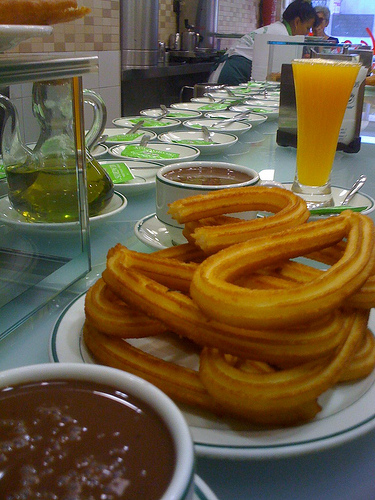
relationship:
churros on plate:
[82, 187, 373, 428] [52, 261, 374, 461]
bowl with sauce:
[0, 363, 196, 499] [2, 379, 177, 500]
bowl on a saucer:
[0, 363, 196, 499] [194, 471, 218, 499]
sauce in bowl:
[2, 379, 177, 500] [0, 363, 196, 499]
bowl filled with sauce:
[0, 363, 196, 499] [2, 379, 177, 500]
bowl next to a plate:
[0, 363, 196, 499] [52, 261, 374, 461]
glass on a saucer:
[291, 58, 361, 201] [264, 182, 374, 216]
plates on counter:
[3, 78, 374, 460] [1, 80, 374, 500]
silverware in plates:
[58, 77, 280, 184] [3, 78, 374, 460]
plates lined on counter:
[3, 78, 374, 460] [1, 80, 374, 500]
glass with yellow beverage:
[291, 58, 361, 201] [293, 63, 360, 185]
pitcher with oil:
[0, 82, 114, 223] [6, 153, 115, 224]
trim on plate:
[194, 412, 374, 451] [52, 261, 374, 461]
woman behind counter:
[207, 0, 322, 86] [1, 80, 374, 500]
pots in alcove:
[162, 21, 224, 63] [122, 0, 234, 116]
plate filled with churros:
[52, 261, 374, 461] [82, 187, 373, 428]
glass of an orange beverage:
[291, 58, 361, 201] [293, 63, 360, 185]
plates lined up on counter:
[3, 78, 374, 460] [1, 80, 374, 500]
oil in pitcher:
[6, 153, 115, 224] [0, 82, 114, 223]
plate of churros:
[52, 261, 374, 461] [82, 187, 373, 428]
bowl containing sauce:
[0, 363, 196, 499] [2, 379, 177, 500]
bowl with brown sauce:
[0, 363, 196, 499] [2, 379, 177, 500]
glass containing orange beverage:
[291, 58, 361, 201] [293, 63, 360, 185]